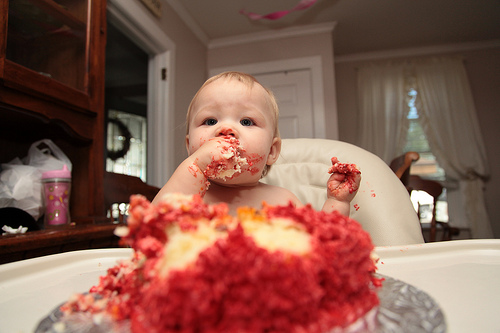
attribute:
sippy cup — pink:
[40, 161, 75, 230]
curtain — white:
[411, 59, 489, 236]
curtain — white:
[356, 67, 411, 164]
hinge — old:
[162, 67, 167, 81]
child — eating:
[131, 57, 361, 275]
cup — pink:
[22, 153, 104, 245]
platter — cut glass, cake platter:
[35, 270, 447, 331]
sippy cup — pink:
[42, 162, 70, 228]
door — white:
[235, 68, 312, 138]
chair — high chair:
[7, 127, 498, 330]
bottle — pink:
[43, 161, 74, 237]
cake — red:
[102, 197, 377, 331]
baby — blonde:
[125, 78, 367, 248]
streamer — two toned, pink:
[224, 0, 331, 38]